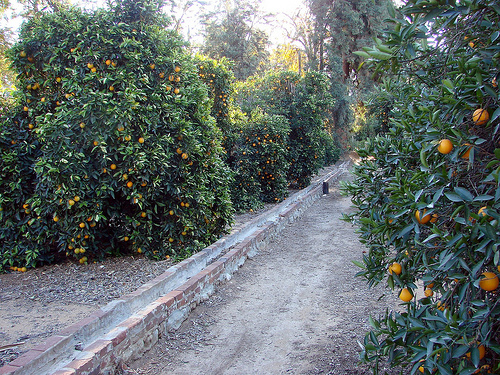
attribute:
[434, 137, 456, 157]
orange — part of a flower, by a brown branch, next to green leaf, by the tip of a leaf, in fruit orchard, on a tree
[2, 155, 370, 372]
brick slab — next to dirt, a path divider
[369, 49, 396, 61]
leaf — small, green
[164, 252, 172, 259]
orange — on the dirt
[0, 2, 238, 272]
large bushes — filled with lemons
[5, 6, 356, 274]
lemon trees — in a fruit orchard, full of leaf patches, along a path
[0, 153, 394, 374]
brown leaves — on the ground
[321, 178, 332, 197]
small brown structur — in a fruit orchard, located along a path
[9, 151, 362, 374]
crevice — in a fruit orchard, between 2 brick area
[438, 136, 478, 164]
yellow lemons — shown close up here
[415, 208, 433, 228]
orange — under main orange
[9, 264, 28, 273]
four oranges — in fruit orchard, on the ground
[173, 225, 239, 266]
leaves — on the edge of wall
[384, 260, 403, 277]
orange — in the fruit orchard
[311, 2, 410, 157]
tall trees — in a fruit orchard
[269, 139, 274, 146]
orange — in middle of orchard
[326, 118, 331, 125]
orange — in back of orchard, in back on tree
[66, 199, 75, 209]
orange — in front of orchard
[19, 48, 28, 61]
orange — high up in orchard, high up in tree